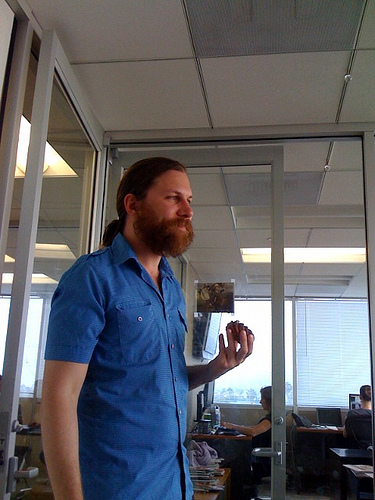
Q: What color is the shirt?
A: Blue.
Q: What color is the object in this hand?
A: Brown.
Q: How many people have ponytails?
A: One.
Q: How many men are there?
A: One.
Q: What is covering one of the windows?
A: Miniblinds.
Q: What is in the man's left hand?
A: A pastry.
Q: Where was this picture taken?
A: An office.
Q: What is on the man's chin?
A: A beard.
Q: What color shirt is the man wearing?
A: Blue.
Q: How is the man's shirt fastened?
A: Buttons.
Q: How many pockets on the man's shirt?
A: 2.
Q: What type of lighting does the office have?
A: Fluorescent.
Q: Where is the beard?
A: On man's face.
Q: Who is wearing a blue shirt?
A: The man with the beard.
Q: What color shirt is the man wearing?
A: Blue.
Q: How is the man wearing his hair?
A: In a ponytail.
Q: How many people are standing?
A: One.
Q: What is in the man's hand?
A: Food.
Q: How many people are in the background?
A: Two.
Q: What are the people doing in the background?
A: On a computer.